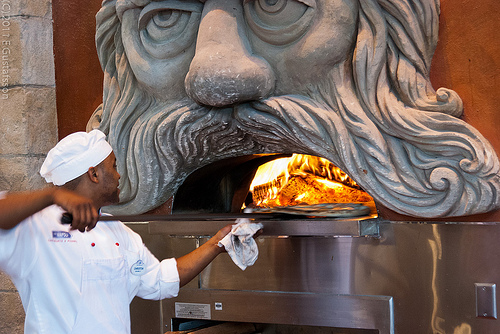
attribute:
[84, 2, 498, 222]
brick oven — huge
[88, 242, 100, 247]
red button — small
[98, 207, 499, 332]
oven — stainless, steel, bottom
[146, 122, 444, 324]
oven — pizza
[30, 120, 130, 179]
hat — chef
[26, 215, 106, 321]
uniform — chef's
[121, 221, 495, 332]
oven — stainless, steel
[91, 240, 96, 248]
button — red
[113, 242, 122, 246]
button — red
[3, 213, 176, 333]
uniform — chef's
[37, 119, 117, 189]
chef hat — white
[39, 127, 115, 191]
hat — chef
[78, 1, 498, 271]
oven — large, stone, faced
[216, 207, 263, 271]
rag — white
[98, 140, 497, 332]
oven — large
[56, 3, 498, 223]
oven — face shaped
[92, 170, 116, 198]
skin — dark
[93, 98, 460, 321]
oven — large, gray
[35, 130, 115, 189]
chefs hat — chef's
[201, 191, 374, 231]
stick — long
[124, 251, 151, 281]
tag — name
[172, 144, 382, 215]
pit — fire, hot coals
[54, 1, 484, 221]
wall — brick, red